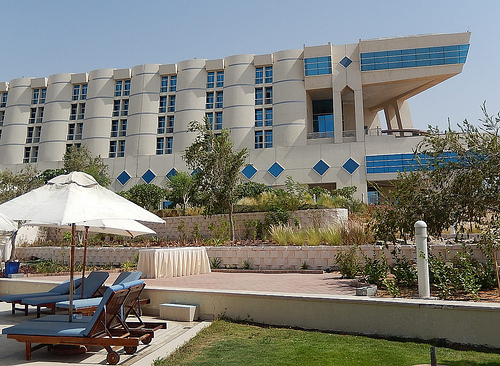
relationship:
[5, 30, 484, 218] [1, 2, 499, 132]
building below sky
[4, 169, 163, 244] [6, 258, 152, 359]
umbrella above chairs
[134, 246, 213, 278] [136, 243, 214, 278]
tablecloth on table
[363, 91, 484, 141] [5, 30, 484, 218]
deck on building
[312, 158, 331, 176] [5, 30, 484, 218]
design on building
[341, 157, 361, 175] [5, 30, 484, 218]
design on building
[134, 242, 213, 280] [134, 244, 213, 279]
table with curtain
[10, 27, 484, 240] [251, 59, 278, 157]
building with windows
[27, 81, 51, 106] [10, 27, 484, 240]
window on building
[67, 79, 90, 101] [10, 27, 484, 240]
window on building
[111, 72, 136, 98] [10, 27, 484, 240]
window on building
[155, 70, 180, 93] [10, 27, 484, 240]
window on building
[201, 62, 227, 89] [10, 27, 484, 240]
window on building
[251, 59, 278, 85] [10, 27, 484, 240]
window on building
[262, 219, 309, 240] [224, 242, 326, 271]
grass above wall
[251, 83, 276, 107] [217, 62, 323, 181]
window in building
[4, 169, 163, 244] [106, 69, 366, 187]
umbrella in building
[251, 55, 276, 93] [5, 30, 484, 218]
window in building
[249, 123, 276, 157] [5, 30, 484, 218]
window in building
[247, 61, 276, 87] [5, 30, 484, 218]
window in building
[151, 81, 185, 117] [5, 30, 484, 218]
window in building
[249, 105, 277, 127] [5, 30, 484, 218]
window in building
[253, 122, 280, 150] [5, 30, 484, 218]
window in building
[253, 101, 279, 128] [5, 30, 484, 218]
window in building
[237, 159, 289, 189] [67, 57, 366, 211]
diamonds on building